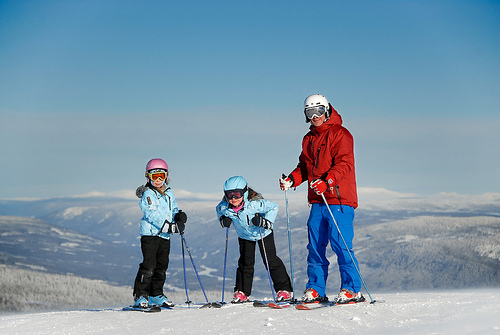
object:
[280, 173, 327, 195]
glove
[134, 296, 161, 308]
shoe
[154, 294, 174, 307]
shoe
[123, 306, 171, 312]
ski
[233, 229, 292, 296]
pants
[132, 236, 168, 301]
pants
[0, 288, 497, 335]
ground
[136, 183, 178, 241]
jacket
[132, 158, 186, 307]
girl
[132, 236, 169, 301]
black pants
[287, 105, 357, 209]
coat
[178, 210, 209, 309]
poles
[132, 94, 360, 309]
adult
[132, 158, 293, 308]
children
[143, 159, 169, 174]
pink helmet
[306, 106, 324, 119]
goggles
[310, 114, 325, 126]
face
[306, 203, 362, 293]
pants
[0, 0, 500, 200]
sky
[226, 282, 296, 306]
pink boots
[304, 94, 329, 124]
helmet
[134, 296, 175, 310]
boots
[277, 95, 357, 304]
adult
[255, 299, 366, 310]
skis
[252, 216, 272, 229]
glove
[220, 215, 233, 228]
glove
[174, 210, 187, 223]
glove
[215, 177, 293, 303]
child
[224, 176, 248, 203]
helmet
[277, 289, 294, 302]
boot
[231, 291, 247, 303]
boot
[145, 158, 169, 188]
head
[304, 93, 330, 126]
head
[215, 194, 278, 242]
jacket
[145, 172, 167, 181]
goggles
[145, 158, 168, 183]
helmet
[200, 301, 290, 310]
skis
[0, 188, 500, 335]
mountain